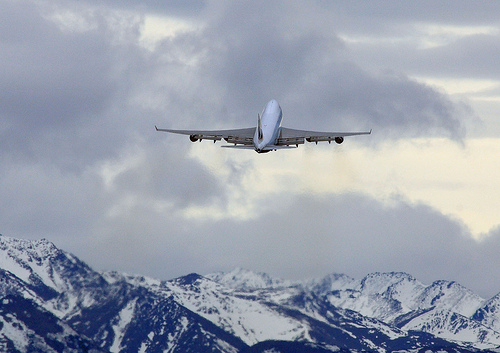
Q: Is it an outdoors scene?
A: Yes, it is outdoors.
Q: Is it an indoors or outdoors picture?
A: It is outdoors.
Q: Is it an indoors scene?
A: No, it is outdoors.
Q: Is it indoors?
A: No, it is outdoors.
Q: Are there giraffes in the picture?
A: No, there are no giraffes.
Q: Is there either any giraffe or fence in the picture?
A: No, there are no giraffes or fences.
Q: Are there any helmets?
A: No, there are no helmets.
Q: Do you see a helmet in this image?
A: No, there are no helmets.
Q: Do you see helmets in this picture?
A: No, there are no helmets.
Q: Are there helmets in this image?
A: No, there are no helmets.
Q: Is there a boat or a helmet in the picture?
A: No, there are no helmets or boats.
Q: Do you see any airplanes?
A: Yes, there is an airplane.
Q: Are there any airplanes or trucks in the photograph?
A: Yes, there is an airplane.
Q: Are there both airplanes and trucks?
A: No, there is an airplane but no trucks.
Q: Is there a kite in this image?
A: No, there are no kites.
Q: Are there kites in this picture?
A: No, there are no kites.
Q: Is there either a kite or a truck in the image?
A: No, there are no kites or trucks.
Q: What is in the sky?
A: The plane is in the sky.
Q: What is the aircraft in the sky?
A: The aircraft is an airplane.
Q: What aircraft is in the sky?
A: The aircraft is an airplane.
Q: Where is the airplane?
A: The airplane is in the sky.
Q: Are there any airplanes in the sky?
A: Yes, there is an airplane in the sky.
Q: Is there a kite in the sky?
A: No, there is an airplane in the sky.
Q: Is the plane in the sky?
A: Yes, the plane is in the sky.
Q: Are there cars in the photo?
A: No, there are no cars.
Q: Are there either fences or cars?
A: No, there are no cars or fences.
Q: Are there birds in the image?
A: No, there are no birds.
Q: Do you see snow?
A: Yes, there is snow.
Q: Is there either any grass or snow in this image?
A: Yes, there is snow.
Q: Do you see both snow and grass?
A: No, there is snow but no grass.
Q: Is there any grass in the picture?
A: No, there is no grass.